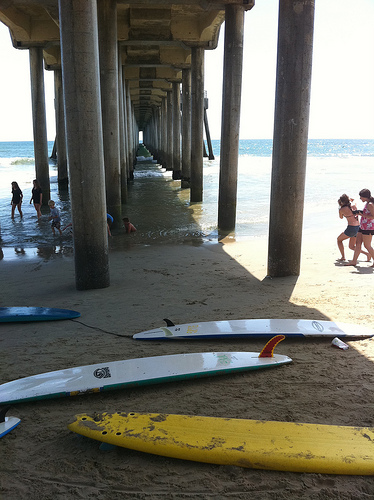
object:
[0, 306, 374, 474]
surfboards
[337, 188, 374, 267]
girls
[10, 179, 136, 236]
people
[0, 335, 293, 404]
surfboard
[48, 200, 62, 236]
child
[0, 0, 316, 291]
dock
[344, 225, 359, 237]
shorts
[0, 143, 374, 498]
beach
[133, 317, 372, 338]
surfboard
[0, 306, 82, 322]
surfboard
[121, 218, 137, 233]
boy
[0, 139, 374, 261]
water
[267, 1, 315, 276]
pillar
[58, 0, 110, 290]
pillar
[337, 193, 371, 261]
child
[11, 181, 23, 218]
person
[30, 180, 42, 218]
person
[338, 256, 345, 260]
foot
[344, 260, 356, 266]
foot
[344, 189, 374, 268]
person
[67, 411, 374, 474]
surfboard